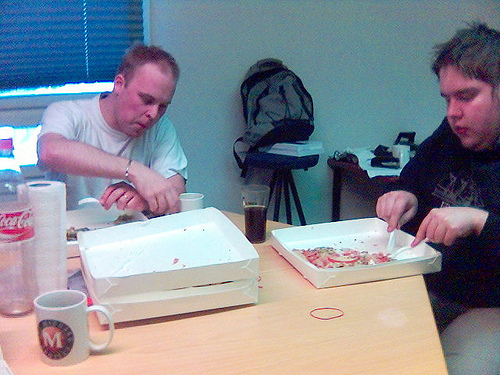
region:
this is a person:
[25, 7, 197, 212]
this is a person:
[360, 11, 495, 288]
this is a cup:
[15, 281, 120, 371]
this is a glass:
[235, 180, 275, 246]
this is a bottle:
[0, 125, 31, 331]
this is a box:
[270, 211, 420, 282]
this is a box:
[65, 197, 265, 312]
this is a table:
[141, 321, 276, 366]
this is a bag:
[220, 50, 311, 162]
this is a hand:
[37, 129, 184, 210]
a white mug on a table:
[28, 289, 116, 364]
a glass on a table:
[241, 183, 272, 243]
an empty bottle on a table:
[0, 137, 42, 317]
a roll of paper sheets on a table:
[15, 175, 70, 310]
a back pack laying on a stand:
[226, 53, 323, 169]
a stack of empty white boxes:
[70, 204, 262, 329]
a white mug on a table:
[176, 189, 206, 210]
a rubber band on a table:
[306, 304, 347, 323]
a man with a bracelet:
[122, 154, 137, 184]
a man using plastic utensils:
[382, 221, 400, 251]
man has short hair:
[104, 37, 193, 118]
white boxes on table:
[62, 197, 267, 351]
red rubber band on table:
[292, 303, 393, 335]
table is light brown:
[174, 301, 393, 373]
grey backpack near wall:
[226, 52, 346, 169]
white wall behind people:
[303, 2, 384, 94]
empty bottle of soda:
[7, 134, 49, 315]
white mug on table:
[30, 294, 97, 374]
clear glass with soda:
[229, 185, 274, 244]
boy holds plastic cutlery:
[370, 195, 440, 276]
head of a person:
[97, 40, 182, 145]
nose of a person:
[142, 99, 159, 123]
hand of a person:
[143, 175, 191, 226]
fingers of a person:
[148, 197, 183, 216]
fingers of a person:
[100, 182, 147, 214]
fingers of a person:
[373, 190, 419, 217]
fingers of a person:
[416, 206, 456, 248]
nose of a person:
[445, 96, 462, 121]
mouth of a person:
[450, 119, 472, 136]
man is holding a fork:
[387, 209, 499, 285]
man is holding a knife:
[373, 193, 418, 262]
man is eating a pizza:
[265, 34, 498, 295]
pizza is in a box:
[269, 217, 442, 288]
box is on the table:
[274, 213, 449, 288]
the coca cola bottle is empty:
[2, 134, 38, 315]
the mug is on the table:
[18, 279, 143, 372]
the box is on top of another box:
[70, 201, 269, 331]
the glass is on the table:
[227, 179, 282, 259]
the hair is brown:
[433, 28, 495, 86]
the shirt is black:
[395, 125, 497, 302]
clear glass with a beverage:
[240, 188, 272, 239]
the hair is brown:
[117, 42, 179, 87]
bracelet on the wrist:
[119, 158, 141, 185]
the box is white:
[72, 205, 262, 287]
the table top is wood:
[5, 206, 452, 371]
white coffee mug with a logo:
[30, 290, 113, 359]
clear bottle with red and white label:
[1, 135, 34, 313]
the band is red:
[309, 301, 342, 323]